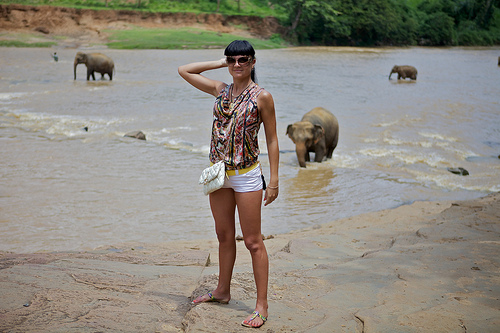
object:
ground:
[396, 228, 500, 326]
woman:
[184, 39, 281, 330]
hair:
[224, 39, 255, 83]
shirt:
[208, 83, 265, 164]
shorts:
[210, 171, 265, 192]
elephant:
[285, 105, 335, 167]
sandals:
[236, 311, 269, 326]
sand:
[4, 295, 147, 333]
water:
[434, 48, 500, 126]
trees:
[295, 4, 499, 51]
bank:
[2, 2, 286, 54]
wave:
[4, 81, 103, 137]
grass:
[115, 31, 205, 52]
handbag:
[197, 155, 227, 197]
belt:
[224, 161, 262, 176]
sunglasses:
[224, 52, 247, 62]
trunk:
[294, 141, 308, 168]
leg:
[314, 146, 327, 165]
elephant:
[71, 51, 114, 82]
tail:
[110, 60, 117, 75]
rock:
[199, 274, 285, 333]